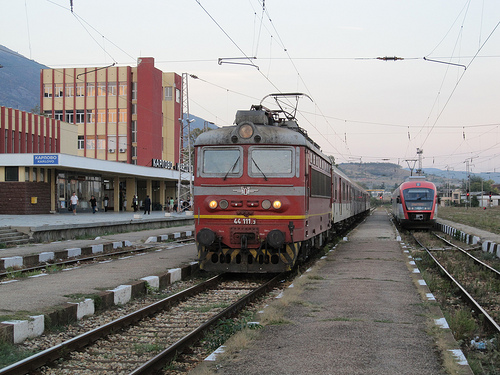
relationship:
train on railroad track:
[180, 100, 371, 272] [1, 220, 500, 374]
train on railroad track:
[385, 174, 438, 229] [1, 220, 500, 374]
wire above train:
[5, 57, 498, 64] [180, 100, 371, 272]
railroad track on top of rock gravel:
[1, 220, 500, 374] [21, 268, 276, 369]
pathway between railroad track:
[185, 203, 475, 374] [1, 220, 500, 374]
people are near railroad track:
[63, 192, 190, 213] [1, 220, 500, 374]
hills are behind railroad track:
[334, 161, 500, 192] [1, 220, 500, 374]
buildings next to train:
[4, 54, 195, 220] [180, 100, 371, 272]